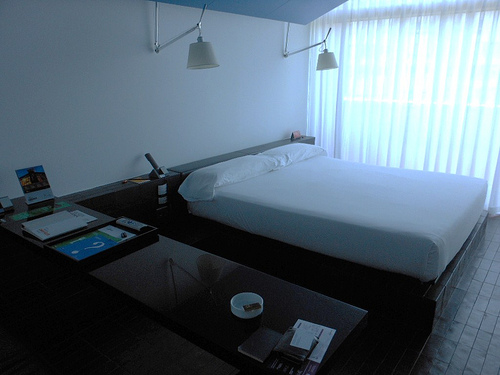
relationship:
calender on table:
[16, 163, 56, 206] [2, 201, 366, 375]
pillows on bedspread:
[177, 143, 330, 204] [176, 142, 487, 278]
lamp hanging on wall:
[153, 1, 218, 70] [1, 1, 312, 199]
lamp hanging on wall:
[284, 22, 339, 72] [1, 1, 312, 199]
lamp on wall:
[153, 1, 218, 70] [1, 1, 312, 199]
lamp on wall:
[284, 22, 339, 72] [1, 1, 312, 199]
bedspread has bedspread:
[176, 142, 487, 278] [176, 142, 487, 278]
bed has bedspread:
[185, 154, 486, 283] [176, 142, 487, 278]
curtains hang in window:
[308, 1, 500, 215] [307, 1, 499, 214]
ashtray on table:
[231, 292, 264, 318] [2, 201, 366, 375]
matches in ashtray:
[245, 302, 261, 311] [231, 292, 264, 318]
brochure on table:
[54, 231, 116, 260] [2, 201, 366, 375]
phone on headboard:
[143, 153, 166, 177] [59, 137, 316, 216]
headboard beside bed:
[59, 137, 316, 216] [185, 154, 486, 283]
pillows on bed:
[177, 143, 330, 204] [185, 154, 486, 283]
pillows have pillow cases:
[177, 143, 330, 204] [177, 142, 325, 200]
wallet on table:
[273, 328, 317, 366] [2, 201, 366, 375]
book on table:
[238, 325, 282, 362] [2, 201, 366, 375]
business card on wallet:
[289, 326, 317, 352] [273, 328, 317, 366]